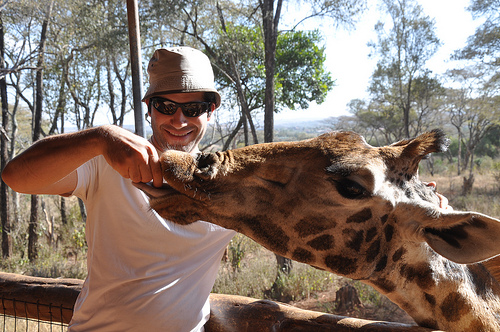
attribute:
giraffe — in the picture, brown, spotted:
[134, 124, 500, 330]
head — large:
[130, 127, 499, 293]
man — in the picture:
[2, 45, 239, 329]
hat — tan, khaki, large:
[139, 44, 223, 113]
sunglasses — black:
[146, 93, 214, 122]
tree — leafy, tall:
[200, 21, 334, 149]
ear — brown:
[392, 199, 499, 267]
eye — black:
[325, 167, 377, 209]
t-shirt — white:
[59, 138, 240, 331]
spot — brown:
[292, 213, 339, 240]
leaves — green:
[197, 21, 335, 112]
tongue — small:
[129, 176, 178, 201]